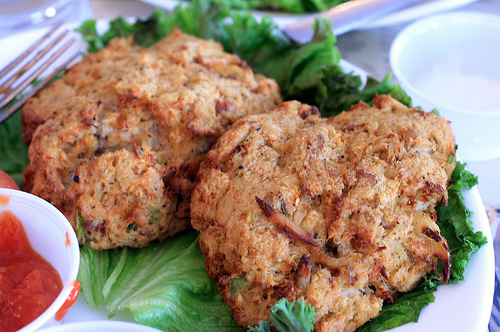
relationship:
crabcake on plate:
[192, 94, 456, 328] [0, 12, 496, 330]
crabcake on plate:
[21, 27, 281, 251] [0, 12, 496, 330]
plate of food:
[464, 272, 489, 329] [17, 9, 457, 330]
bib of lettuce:
[6, 23, 461, 330] [76, 245, 221, 330]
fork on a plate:
[1, 18, 83, 118] [445, 235, 495, 330]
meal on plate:
[27, 37, 459, 330] [24, 50, 487, 320]